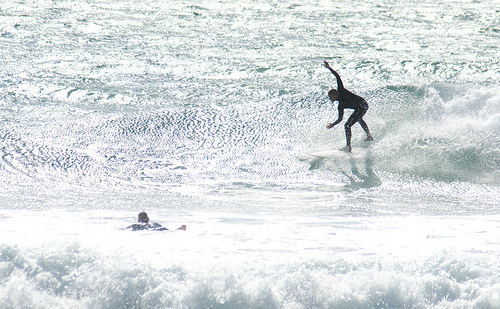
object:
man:
[312, 61, 374, 154]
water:
[1, 2, 490, 210]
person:
[126, 206, 188, 233]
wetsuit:
[342, 87, 368, 137]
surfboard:
[315, 143, 368, 163]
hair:
[328, 87, 336, 95]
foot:
[343, 144, 352, 153]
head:
[329, 85, 338, 105]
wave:
[380, 85, 498, 201]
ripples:
[22, 142, 365, 202]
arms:
[324, 55, 341, 130]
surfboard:
[125, 228, 199, 237]